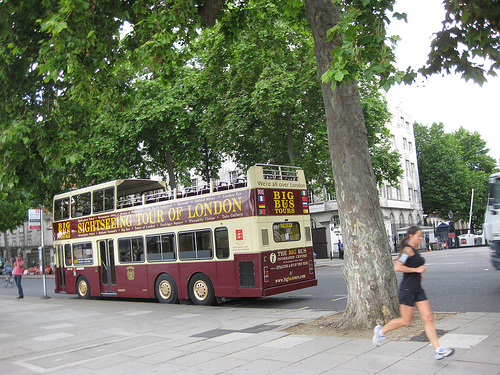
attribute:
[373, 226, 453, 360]
girl — running, jogging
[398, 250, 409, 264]
band — grey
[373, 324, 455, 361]
shoes — white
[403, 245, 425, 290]
top — black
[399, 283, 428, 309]
shorts — black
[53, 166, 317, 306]
bus — large, parked, red, beige, maroon, white, owned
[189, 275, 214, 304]
wheel — small, black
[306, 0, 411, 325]
trunk — brown, long, live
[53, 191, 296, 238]
writing — yellow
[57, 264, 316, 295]
bottom — red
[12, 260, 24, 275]
shirt — pink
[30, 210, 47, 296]
signpost — white, blue, red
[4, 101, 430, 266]
architecture — urban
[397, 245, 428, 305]
clothing — black, athletic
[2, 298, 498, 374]
sidewalk — paved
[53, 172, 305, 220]
deck — open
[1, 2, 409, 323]
trees — leafy, green